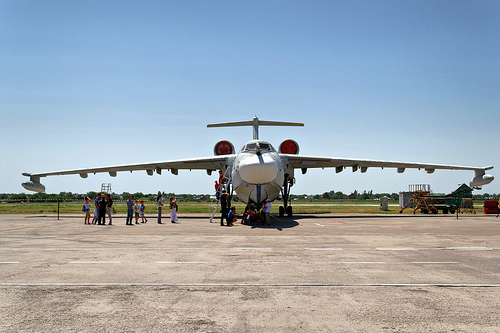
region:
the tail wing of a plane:
[206, 116, 319, 131]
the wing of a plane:
[14, 153, 242, 183]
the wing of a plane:
[284, 148, 498, 181]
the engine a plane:
[277, 133, 300, 161]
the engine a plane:
[208, 134, 239, 165]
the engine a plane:
[20, 176, 53, 196]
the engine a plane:
[466, 173, 493, 192]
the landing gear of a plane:
[274, 189, 299, 221]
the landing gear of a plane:
[244, 202, 273, 231]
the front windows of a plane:
[239, 140, 276, 154]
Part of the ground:
[203, 304, 272, 324]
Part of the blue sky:
[139, 62, 241, 96]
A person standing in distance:
[153, 192, 165, 226]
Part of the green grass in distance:
[22, 205, 33, 210]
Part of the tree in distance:
[391, 192, 398, 200]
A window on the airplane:
[244, 141, 259, 153]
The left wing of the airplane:
[283, 149, 497, 192]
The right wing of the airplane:
[18, 152, 236, 194]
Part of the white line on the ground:
[101, 282, 119, 287]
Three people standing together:
[90, 189, 115, 226]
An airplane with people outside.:
[45, 108, 493, 257]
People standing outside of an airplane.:
[82, 188, 189, 254]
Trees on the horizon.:
[295, 185, 390, 230]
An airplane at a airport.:
[20, 155, 430, 292]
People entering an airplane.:
[191, 168, 261, 240]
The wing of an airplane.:
[285, 147, 485, 211]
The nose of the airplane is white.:
[231, 148, 284, 181]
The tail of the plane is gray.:
[202, 105, 326, 203]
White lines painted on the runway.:
[13, 230, 415, 316]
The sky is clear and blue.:
[37, 33, 392, 165]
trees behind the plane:
[8, 194, 66, 201]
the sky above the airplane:
[13, 15, 452, 121]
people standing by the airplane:
[80, 192, 176, 225]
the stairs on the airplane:
[208, 173, 230, 200]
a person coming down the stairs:
[210, 176, 220, 198]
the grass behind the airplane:
[304, 201, 374, 216]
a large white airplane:
[18, 100, 496, 236]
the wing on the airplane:
[290, 152, 487, 180]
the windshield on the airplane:
[245, 140, 271, 150]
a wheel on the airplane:
[278, 205, 297, 212]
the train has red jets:
[159, 104, 362, 173]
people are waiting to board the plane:
[73, 139, 268, 279]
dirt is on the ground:
[97, 253, 130, 288]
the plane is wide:
[10, 156, 488, 207]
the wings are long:
[288, 143, 448, 211]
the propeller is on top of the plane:
[207, 98, 429, 222]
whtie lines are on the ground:
[120, 250, 389, 287]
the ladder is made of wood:
[407, 176, 475, 266]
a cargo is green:
[389, 186, 491, 279]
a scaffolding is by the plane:
[364, 180, 497, 232]